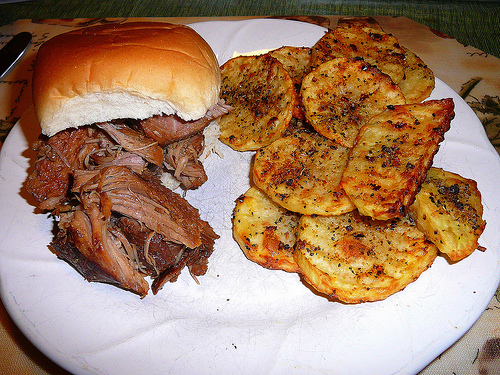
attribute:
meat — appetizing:
[75, 160, 176, 277]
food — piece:
[55, 138, 223, 303]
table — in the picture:
[8, 11, 499, 374]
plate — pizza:
[184, 17, 327, 66]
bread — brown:
[30, 17, 221, 137]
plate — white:
[0, 72, 387, 372]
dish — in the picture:
[1, 65, 489, 368]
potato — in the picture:
[338, 94, 456, 223]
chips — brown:
[210, 15, 486, 306]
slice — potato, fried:
[338, 98, 455, 222]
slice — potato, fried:
[250, 133, 354, 215]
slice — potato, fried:
[300, 56, 405, 148]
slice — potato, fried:
[216, 53, 293, 151]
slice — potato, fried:
[265, 45, 316, 122]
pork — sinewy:
[43, 137, 207, 275]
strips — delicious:
[224, 24, 489, 308]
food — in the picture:
[257, 53, 462, 303]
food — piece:
[37, 40, 480, 301]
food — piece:
[21, 15, 491, 307]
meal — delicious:
[32, 14, 484, 304]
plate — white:
[0, 19, 497, 372]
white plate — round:
[8, 14, 494, 373]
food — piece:
[407, 164, 494, 265]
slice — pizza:
[346, 100, 453, 221]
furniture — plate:
[1, 12, 498, 373]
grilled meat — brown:
[46, 111, 202, 266]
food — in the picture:
[258, 130, 382, 235]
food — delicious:
[214, 16, 489, 306]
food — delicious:
[17, 100, 239, 300]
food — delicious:
[27, 17, 222, 141]